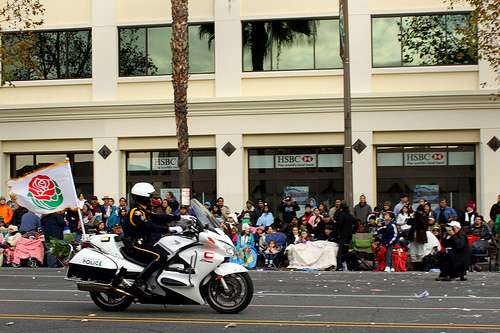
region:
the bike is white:
[64, 195, 255, 315]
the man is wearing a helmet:
[126, 180, 161, 211]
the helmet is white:
[128, 180, 159, 206]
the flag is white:
[3, 150, 96, 247]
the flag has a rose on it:
[21, 175, 71, 205]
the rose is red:
[26, 172, 60, 206]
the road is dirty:
[1, 260, 499, 330]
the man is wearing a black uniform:
[119, 204, 183, 302]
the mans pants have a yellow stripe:
[131, 244, 160, 265]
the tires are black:
[79, 268, 256, 315]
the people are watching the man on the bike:
[1, 172, 498, 287]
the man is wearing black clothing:
[120, 175, 193, 305]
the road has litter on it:
[1, 263, 499, 331]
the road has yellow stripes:
[0, 292, 499, 329]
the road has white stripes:
[0, 265, 496, 320]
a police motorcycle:
[43, 171, 274, 328]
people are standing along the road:
[2, 174, 499, 306]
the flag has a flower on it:
[8, 148, 98, 242]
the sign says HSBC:
[266, 146, 328, 176]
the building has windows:
[1, 7, 497, 87]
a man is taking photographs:
[422, 212, 487, 290]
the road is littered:
[6, 255, 498, 327]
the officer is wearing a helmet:
[53, 175, 258, 323]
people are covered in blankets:
[225, 212, 354, 276]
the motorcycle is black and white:
[41, 184, 292, 312]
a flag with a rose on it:
[10, 172, 105, 237]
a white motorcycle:
[71, 226, 278, 295]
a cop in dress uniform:
[106, 180, 215, 327]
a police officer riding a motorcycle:
[16, 165, 294, 318]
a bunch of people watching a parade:
[4, 178, 498, 278]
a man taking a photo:
[431, 219, 498, 290]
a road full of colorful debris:
[11, 270, 498, 323]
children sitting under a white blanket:
[287, 227, 340, 270]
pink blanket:
[18, 230, 51, 283]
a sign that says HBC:
[249, 149, 348, 167]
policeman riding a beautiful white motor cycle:
[47, 165, 272, 306]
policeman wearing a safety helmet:
[51, 168, 283, 309]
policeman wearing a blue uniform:
[41, 163, 251, 320]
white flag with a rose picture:
[0, 116, 114, 274]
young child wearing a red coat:
[370, 238, 413, 275]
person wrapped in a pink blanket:
[15, 229, 48, 271]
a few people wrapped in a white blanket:
[262, 223, 347, 288]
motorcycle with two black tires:
[36, 265, 281, 308]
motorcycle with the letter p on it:
[56, 188, 269, 309]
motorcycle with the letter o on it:
[65, 173, 258, 303]